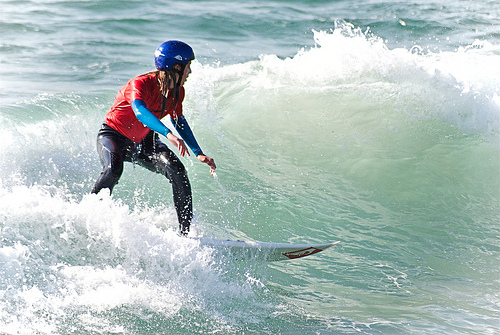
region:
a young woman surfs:
[46, 29, 443, 299]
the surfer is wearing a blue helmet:
[71, 17, 313, 313]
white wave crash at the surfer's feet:
[41, 206, 186, 295]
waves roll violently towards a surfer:
[277, 30, 482, 127]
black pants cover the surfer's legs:
[91, 141, 181, 193]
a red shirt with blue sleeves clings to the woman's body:
[109, 36, 209, 157]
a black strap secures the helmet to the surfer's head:
[160, 67, 185, 91]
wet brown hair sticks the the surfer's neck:
[161, 74, 176, 89]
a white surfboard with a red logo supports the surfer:
[213, 240, 355, 262]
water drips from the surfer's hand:
[194, 152, 231, 183]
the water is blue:
[330, 150, 407, 238]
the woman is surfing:
[85, 40, 355, 270]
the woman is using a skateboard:
[80, 40, 355, 275]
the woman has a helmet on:
[90, 40, 405, 295]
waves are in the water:
[55, 55, 435, 295]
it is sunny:
[5, 45, 495, 330]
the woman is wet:
[50, 50, 430, 310]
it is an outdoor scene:
[5, 45, 495, 325]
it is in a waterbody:
[10, 40, 490, 320]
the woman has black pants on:
[86, 45, 366, 290]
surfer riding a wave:
[55, 40, 429, 288]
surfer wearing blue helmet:
[116, 30, 211, 95]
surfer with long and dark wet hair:
[150, 45, 195, 120]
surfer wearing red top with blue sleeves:
[101, 75, 193, 142]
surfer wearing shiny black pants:
[91, 117, 206, 237]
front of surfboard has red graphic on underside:
[190, 221, 355, 276]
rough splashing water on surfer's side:
[21, 207, 231, 312]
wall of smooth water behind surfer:
[12, 85, 112, 195]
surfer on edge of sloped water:
[145, 35, 456, 306]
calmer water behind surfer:
[31, 11, 306, 76]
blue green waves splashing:
[1, 1, 494, 329]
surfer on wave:
[72, 30, 346, 273]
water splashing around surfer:
[5, 140, 242, 317]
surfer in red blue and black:
[89, 32, 219, 236]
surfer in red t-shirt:
[92, 33, 215, 237]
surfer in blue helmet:
[92, 36, 216, 246]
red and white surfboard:
[205, 226, 345, 268]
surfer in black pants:
[92, 35, 222, 241]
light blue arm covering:
[118, 92, 190, 154]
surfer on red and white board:
[92, 34, 347, 260]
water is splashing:
[21, 211, 183, 298]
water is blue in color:
[346, 231, 440, 294]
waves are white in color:
[253, 40, 468, 106]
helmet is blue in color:
[152, 39, 186, 64]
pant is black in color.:
[101, 138, 129, 170]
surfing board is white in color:
[201, 213, 293, 290]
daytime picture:
[31, 42, 450, 271]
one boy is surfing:
[63, 23, 403, 290]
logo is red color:
[286, 234, 319, 266]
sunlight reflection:
[8, 17, 62, 91]